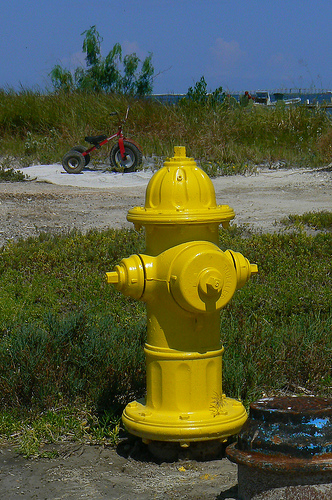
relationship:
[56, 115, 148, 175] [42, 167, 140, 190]
bicycle parked on sand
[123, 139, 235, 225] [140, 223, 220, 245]
hydrant cover has shadow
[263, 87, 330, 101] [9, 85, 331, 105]
bridge on horizon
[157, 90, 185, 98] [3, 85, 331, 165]
water behind grass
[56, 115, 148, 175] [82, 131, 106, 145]
bicycle has seat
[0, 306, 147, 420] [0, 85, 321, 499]
weeds on ground